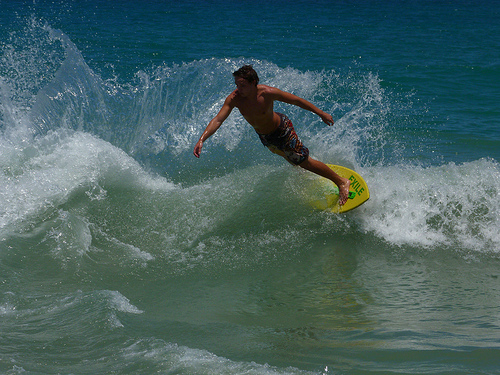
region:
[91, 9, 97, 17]
water drop in air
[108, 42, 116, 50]
water drop in air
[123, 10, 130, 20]
water drop in air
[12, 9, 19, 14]
water drop in air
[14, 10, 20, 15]
water drop in air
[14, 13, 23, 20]
water drop in air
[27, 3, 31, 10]
water drop in air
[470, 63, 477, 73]
water drop in air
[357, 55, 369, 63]
water drop in air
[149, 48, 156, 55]
water drop in air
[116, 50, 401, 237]
a surfer riding a wave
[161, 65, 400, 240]
a man on a surfboard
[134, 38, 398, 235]
a man on a yellow surfboard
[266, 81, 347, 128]
the arm of a man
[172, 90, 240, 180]
the arm of a man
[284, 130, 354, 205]
the legs of a man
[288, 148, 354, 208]
the leg of a surfer on his board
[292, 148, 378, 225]
the tip of the surfboard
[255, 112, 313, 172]
the bathing trunks worn by a surfer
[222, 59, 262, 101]
the head of a surfer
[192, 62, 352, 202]
A man surf boarding in the ocean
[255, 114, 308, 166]
A man's multi-colored swimming trunks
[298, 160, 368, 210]
A yellow surf board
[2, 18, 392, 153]
A large splash of water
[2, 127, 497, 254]
A wave being ridden by a surfer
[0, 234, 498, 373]
The shallow water close to the shore line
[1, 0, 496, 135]
The deeper water past the sand bar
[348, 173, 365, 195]
A decal on the surf board that reads, "EXILE"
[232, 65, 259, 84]
A surfer's wet, brown hair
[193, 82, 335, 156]
A surfer outstretches his arms to gain balance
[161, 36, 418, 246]
a young man surfing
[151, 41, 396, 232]
a man on a surfboard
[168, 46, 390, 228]
a person riding a wave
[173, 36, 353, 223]
a man with short brown hair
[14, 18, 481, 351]
waves in the ocean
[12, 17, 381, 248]
water splashing around a surfer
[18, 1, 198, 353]
the ocean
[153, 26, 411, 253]
a man balancing on a board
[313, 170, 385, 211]
yellow surf board in water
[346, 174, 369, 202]
name on board in green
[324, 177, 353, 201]
feet on the surfboard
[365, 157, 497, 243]
white caps in the water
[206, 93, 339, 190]
person leaning to one side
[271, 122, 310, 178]
multicolored swim pants on surfer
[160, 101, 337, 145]
arms are outstretched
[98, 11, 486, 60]
water behind waves is calm and blue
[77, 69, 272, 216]
person looking at the wave